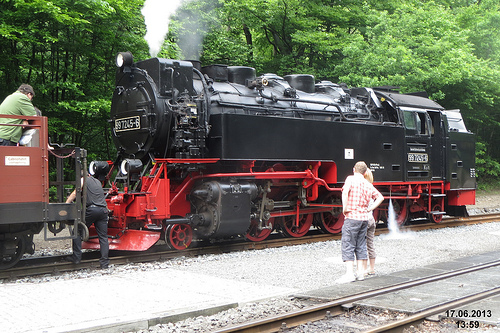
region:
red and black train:
[80, 45, 490, 235]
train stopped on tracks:
[99, 35, 483, 237]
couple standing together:
[334, 143, 405, 282]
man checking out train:
[67, 157, 116, 274]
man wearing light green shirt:
[1, 78, 41, 166]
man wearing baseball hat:
[4, 80, 43, 165]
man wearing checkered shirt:
[334, 150, 375, 287]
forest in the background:
[6, 6, 493, 98]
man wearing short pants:
[343, 152, 375, 285]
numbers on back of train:
[106, 98, 154, 140]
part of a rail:
[406, 274, 433, 295]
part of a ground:
[266, 248, 291, 270]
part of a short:
[333, 230, 364, 263]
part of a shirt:
[343, 189, 359, 214]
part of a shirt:
[353, 176, 364, 190]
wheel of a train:
[169, 235, 218, 261]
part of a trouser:
[92, 209, 113, 232]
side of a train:
[225, 80, 318, 217]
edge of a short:
[338, 249, 360, 264]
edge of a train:
[451, 127, 483, 192]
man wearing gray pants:
[336, 217, 370, 267]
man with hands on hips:
[337, 193, 376, 226]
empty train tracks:
[190, 259, 497, 331]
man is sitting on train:
[0, 78, 50, 146]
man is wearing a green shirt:
[2, 77, 42, 149]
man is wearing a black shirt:
[64, 170, 116, 266]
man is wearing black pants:
[57, 168, 120, 265]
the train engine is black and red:
[67, 45, 482, 254]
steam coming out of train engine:
[130, 5, 182, 64]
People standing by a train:
[330, 151, 400, 283]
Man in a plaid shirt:
[332, 161, 384, 227]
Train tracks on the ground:
[268, 277, 488, 331]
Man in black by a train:
[65, 163, 124, 255]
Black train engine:
[86, 58, 483, 243]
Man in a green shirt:
[1, 79, 62, 170]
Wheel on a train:
[159, 201, 213, 258]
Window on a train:
[390, 100, 470, 137]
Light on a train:
[116, 51, 126, 69]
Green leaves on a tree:
[292, 5, 495, 87]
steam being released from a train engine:
[178, 0, 210, 57]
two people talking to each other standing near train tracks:
[331, 162, 385, 282]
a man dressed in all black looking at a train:
[66, 167, 109, 269]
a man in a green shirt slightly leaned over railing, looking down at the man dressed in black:
[1, 84, 38, 143]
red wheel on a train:
[166, 222, 194, 250]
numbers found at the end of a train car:
[113, 116, 142, 131]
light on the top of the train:
[115, 50, 129, 69]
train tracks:
[212, 260, 499, 332]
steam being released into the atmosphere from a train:
[381, 199, 406, 238]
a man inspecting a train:
[63, 169, 109, 267]